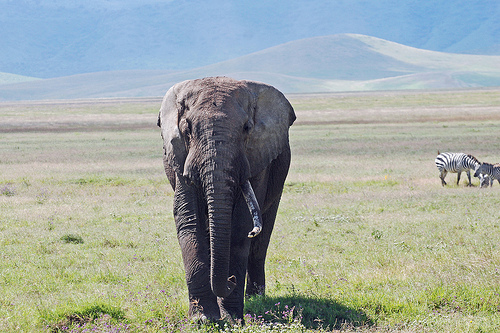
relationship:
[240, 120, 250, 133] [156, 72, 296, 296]
eyes in head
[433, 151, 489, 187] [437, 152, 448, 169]
zebras have stripes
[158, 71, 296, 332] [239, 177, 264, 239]
elephant has tusk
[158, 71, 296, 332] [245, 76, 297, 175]
elephant has ear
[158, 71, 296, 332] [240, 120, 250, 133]
elephant has eyes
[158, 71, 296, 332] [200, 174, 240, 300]
elephant has trunk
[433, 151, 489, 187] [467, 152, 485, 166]
zebras have mane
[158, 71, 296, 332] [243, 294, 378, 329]
elephant has shadow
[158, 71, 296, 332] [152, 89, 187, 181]
elephant has ear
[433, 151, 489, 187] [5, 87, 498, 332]
zebras in field